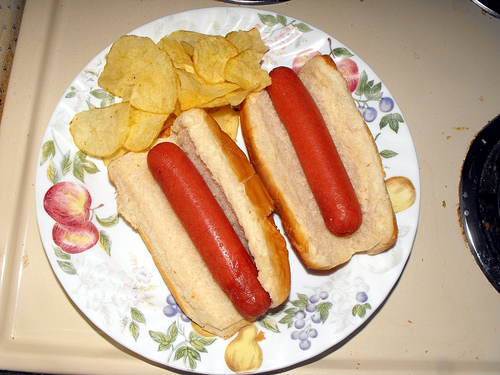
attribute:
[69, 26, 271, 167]
chips — potatoes, yellow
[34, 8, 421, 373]
plate — floral, decorative, white, sitting, next, round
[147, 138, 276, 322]
weiner — cooked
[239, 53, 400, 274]
bun — bread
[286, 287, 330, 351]
grapes — purple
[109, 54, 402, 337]
hotdogs — plain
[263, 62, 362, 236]
hotdog — tan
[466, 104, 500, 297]
burner — silver